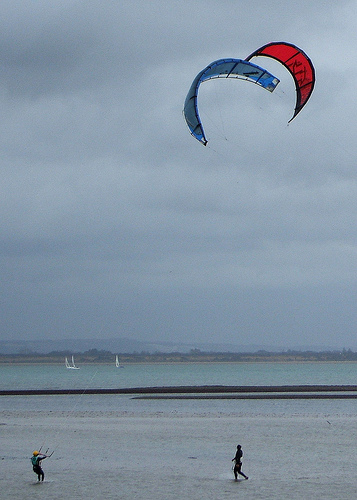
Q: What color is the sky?
A: Blue.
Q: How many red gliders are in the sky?
A: 1.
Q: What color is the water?
A: Light blue.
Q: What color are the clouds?
A: White.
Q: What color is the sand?
A: Gray.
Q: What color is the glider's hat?
A: Yellow.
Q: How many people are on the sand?
A: 2.